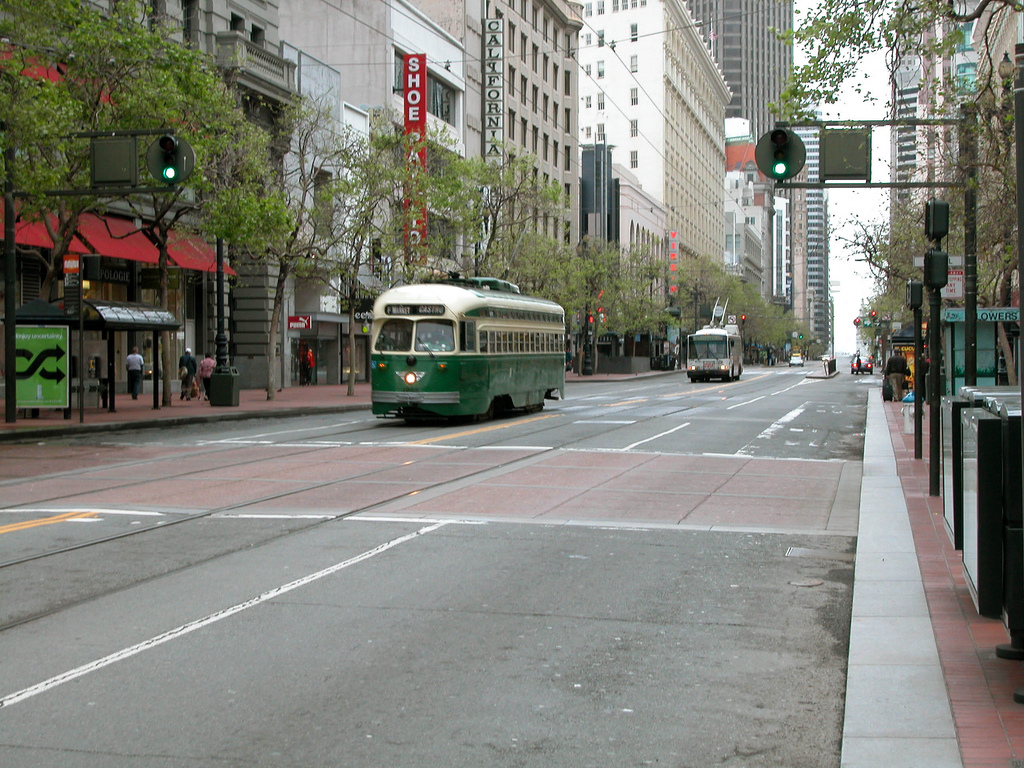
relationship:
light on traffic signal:
[161, 165, 177, 179] [150, 122, 192, 189]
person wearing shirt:
[124, 346, 144, 400] [122, 355, 149, 369]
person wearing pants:
[125, 351, 149, 401] [127, 373, 145, 395]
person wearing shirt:
[170, 349, 199, 401] [179, 355, 192, 377]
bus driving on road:
[366, 273, 570, 423] [1, 360, 872, 758]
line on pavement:
[0, 522, 454, 710] [3, 366, 868, 764]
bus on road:
[680, 327, 750, 386] [1, 360, 872, 758]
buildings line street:
[1, 1, 831, 393] [0, 364, 873, 764]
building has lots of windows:
[407, 0, 580, 363] [498, 0, 572, 245]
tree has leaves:
[1, 0, 298, 413] [0, 0, 292, 256]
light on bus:
[405, 368, 416, 388] [366, 273, 570, 423]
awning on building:
[0, 202, 242, 280] [0, 0, 484, 400]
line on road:
[3, 509, 94, 536] [1, 360, 872, 758]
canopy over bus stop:
[62, 303, 179, 330] [75, 303, 181, 410]